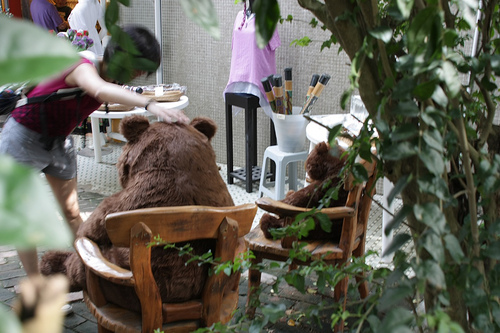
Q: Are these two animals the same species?
A: Yes, all the animals are bears.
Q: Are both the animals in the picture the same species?
A: Yes, all the animals are bears.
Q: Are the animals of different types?
A: No, all the animals are bears.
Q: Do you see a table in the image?
A: Yes, there is a table.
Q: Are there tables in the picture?
A: Yes, there is a table.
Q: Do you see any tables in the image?
A: Yes, there is a table.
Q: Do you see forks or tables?
A: Yes, there is a table.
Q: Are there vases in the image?
A: No, there are no vases.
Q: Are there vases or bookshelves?
A: No, there are no vases or bookshelves.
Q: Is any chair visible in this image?
A: Yes, there is a chair.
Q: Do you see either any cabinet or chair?
A: Yes, there is a chair.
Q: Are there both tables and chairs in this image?
A: Yes, there are both a chair and a table.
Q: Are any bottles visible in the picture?
A: No, there are no bottles.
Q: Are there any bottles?
A: No, there are no bottles.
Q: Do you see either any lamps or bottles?
A: No, there are no bottles or lamps.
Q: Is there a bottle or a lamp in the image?
A: No, there are no bottles or lamps.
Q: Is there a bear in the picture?
A: Yes, there is a bear.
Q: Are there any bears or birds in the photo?
A: Yes, there is a bear.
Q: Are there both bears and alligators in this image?
A: No, there is a bear but no alligators.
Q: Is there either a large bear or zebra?
A: Yes, there is a large bear.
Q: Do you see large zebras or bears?
A: Yes, there is a large bear.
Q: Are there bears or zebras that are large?
A: Yes, the bear is large.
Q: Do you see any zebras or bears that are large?
A: Yes, the bear is large.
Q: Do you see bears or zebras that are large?
A: Yes, the bear is large.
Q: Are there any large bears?
A: Yes, there is a large bear.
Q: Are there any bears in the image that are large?
A: Yes, there is a bear that is large.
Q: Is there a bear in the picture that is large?
A: Yes, there is a bear that is large.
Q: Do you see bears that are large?
A: Yes, there is a bear that is large.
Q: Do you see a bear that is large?
A: Yes, there is a bear that is large.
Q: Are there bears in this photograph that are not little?
A: Yes, there is a large bear.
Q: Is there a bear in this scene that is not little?
A: Yes, there is a large bear.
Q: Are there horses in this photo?
A: No, there are no horses.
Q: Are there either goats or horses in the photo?
A: No, there are no horses or goats.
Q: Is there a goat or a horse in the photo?
A: No, there are no horses or goats.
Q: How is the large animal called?
A: The animal is a bear.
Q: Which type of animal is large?
A: The animal is a bear.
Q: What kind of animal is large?
A: The animal is a bear.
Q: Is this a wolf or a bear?
A: This is a bear.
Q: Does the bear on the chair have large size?
A: Yes, the bear is large.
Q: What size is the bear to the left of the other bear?
A: The bear is large.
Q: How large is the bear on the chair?
A: The bear is large.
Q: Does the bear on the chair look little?
A: No, the bear is large.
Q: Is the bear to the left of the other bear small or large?
A: The bear is large.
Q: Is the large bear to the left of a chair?
A: Yes, the bear is to the left of a chair.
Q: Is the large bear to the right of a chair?
A: No, the bear is to the left of a chair.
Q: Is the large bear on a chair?
A: Yes, the bear is on a chair.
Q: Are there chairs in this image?
A: Yes, there is a chair.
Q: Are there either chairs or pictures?
A: Yes, there is a chair.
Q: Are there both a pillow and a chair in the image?
A: No, there is a chair but no pillows.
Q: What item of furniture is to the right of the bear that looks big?
A: The piece of furniture is a chair.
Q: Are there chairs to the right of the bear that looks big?
A: Yes, there is a chair to the right of the bear.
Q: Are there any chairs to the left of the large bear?
A: No, the chair is to the right of the bear.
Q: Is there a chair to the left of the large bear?
A: No, the chair is to the right of the bear.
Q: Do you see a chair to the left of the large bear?
A: No, the chair is to the right of the bear.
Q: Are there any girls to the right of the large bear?
A: No, there is a chair to the right of the bear.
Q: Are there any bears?
A: Yes, there is a bear.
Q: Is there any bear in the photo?
A: Yes, there is a bear.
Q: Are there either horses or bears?
A: Yes, there is a bear.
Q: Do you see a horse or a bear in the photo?
A: Yes, there is a bear.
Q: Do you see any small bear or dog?
A: Yes, there is a small bear.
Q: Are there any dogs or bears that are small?
A: Yes, the bear is small.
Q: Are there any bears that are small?
A: Yes, there is a small bear.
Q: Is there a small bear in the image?
A: Yes, there is a small bear.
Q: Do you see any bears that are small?
A: Yes, there is a bear that is small.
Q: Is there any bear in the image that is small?
A: Yes, there is a bear that is small.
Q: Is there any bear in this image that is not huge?
A: Yes, there is a small bear.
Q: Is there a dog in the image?
A: No, there are no dogs.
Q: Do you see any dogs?
A: No, there are no dogs.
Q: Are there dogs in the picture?
A: No, there are no dogs.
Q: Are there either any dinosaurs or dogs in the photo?
A: No, there are no dogs or dinosaurs.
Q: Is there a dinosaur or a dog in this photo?
A: No, there are no dogs or dinosaurs.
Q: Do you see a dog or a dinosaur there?
A: No, there are no dogs or dinosaurs.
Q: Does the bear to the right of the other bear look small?
A: Yes, the bear is small.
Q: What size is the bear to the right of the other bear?
A: The bear is small.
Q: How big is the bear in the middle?
A: The bear is small.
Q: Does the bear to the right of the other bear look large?
A: No, the bear is small.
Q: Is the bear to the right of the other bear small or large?
A: The bear is small.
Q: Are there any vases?
A: No, there are no vases.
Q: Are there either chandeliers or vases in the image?
A: No, there are no vases or chandeliers.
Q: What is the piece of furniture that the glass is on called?
A: The piece of furniture is a table.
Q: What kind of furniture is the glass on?
A: The glass is on the table.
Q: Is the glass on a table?
A: Yes, the glass is on a table.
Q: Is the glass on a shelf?
A: No, the glass is on a table.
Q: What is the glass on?
A: The glass is on the table.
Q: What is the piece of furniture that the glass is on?
A: The piece of furniture is a table.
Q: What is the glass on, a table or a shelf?
A: The glass is on a table.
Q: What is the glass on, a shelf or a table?
A: The glass is on a table.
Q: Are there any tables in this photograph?
A: Yes, there is a table.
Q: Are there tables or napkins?
A: Yes, there is a table.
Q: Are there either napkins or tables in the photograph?
A: Yes, there is a table.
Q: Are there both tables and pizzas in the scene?
A: No, there is a table but no pizzas.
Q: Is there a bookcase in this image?
A: No, there are no bookcases.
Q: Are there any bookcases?
A: No, there are no bookcases.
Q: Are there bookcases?
A: No, there are no bookcases.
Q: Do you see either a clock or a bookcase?
A: No, there are no bookcases or clocks.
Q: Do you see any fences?
A: No, there are no fences.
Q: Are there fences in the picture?
A: No, there are no fences.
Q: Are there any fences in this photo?
A: No, there are no fences.